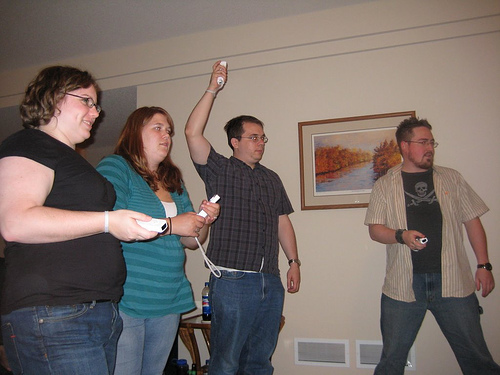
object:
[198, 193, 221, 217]
command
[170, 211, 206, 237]
hand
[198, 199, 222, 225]
hand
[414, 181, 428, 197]
skull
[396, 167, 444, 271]
shirt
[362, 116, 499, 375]
man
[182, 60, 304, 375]
man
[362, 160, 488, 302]
shirt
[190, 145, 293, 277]
shirt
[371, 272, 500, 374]
jeans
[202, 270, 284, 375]
jeans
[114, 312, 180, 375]
jeans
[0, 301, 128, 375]
jeans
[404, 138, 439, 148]
glasses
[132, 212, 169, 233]
controller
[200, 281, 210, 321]
pepsi bottle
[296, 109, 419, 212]
picture frame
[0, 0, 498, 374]
wall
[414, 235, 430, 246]
controller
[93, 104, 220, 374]
woman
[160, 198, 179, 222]
shirt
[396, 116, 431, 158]
short hair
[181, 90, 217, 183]
arm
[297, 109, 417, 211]
painting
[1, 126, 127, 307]
shirt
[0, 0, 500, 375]
game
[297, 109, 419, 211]
picture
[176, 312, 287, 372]
table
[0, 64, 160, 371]
person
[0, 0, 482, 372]
room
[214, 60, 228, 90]
game command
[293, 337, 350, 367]
vent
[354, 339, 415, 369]
vent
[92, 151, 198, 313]
shirt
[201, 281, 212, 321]
bottle